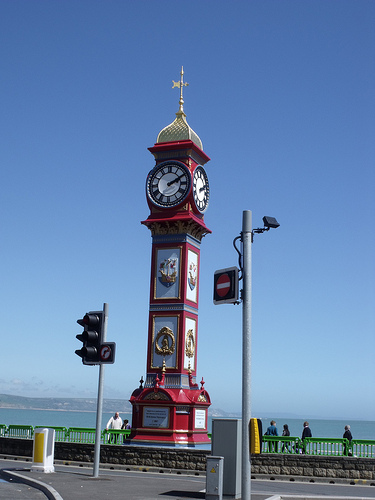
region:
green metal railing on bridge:
[0, 421, 369, 459]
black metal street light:
[74, 300, 106, 368]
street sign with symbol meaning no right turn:
[96, 338, 119, 366]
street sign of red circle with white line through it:
[208, 263, 241, 305]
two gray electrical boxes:
[200, 414, 251, 499]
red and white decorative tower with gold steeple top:
[117, 62, 215, 456]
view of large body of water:
[1, 403, 374, 438]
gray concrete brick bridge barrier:
[1, 433, 374, 489]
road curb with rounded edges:
[1, 452, 372, 499]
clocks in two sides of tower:
[140, 148, 212, 235]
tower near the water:
[147, 56, 214, 424]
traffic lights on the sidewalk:
[71, 305, 96, 362]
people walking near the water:
[261, 415, 359, 453]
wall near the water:
[10, 433, 374, 485]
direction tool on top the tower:
[167, 61, 200, 111]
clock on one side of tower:
[139, 161, 193, 204]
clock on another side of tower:
[191, 171, 209, 212]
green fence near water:
[263, 428, 374, 459]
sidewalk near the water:
[90, 477, 141, 497]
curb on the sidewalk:
[30, 476, 42, 495]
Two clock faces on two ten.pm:
[144, 160, 210, 215]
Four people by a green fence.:
[262, 420, 353, 457]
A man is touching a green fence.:
[104, 410, 125, 444]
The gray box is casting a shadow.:
[160, 455, 223, 497]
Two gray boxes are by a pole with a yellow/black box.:
[202, 415, 263, 497]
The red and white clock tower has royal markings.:
[133, 61, 209, 448]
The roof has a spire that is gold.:
[147, 66, 207, 158]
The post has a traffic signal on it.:
[76, 303, 116, 476]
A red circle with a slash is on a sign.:
[212, 266, 250, 304]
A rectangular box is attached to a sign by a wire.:
[211, 216, 277, 302]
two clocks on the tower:
[148, 163, 209, 211]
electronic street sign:
[212, 268, 239, 303]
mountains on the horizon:
[0, 394, 132, 412]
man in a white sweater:
[104, 412, 123, 437]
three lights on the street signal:
[75, 310, 104, 362]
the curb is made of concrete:
[2, 467, 61, 499]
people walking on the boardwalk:
[266, 421, 353, 452]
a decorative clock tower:
[129, 65, 210, 447]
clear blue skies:
[2, 2, 371, 402]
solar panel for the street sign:
[261, 216, 278, 227]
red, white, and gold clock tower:
[127, 59, 223, 468]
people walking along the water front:
[93, 405, 370, 463]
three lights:
[74, 309, 98, 364]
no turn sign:
[99, 341, 113, 361]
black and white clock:
[148, 163, 189, 206]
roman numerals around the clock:
[143, 167, 190, 206]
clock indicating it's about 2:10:
[144, 161, 191, 210]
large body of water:
[2, 406, 374, 460]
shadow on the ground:
[163, 487, 206, 498]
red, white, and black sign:
[210, 269, 238, 299]